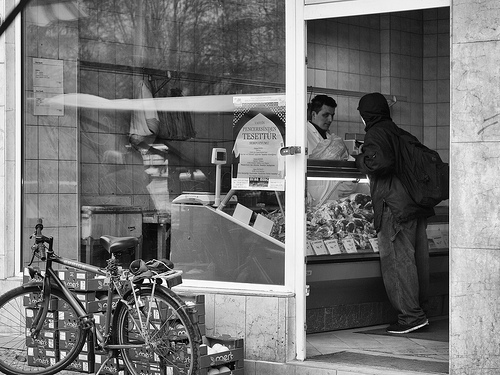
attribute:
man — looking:
[357, 89, 448, 334]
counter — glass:
[168, 158, 452, 334]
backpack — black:
[379, 120, 452, 206]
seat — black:
[98, 234, 139, 253]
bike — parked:
[1, 218, 199, 374]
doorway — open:
[306, 7, 448, 374]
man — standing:
[305, 93, 352, 161]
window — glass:
[24, 0, 285, 284]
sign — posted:
[231, 94, 288, 191]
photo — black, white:
[1, 0, 499, 374]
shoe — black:
[386, 309, 430, 335]